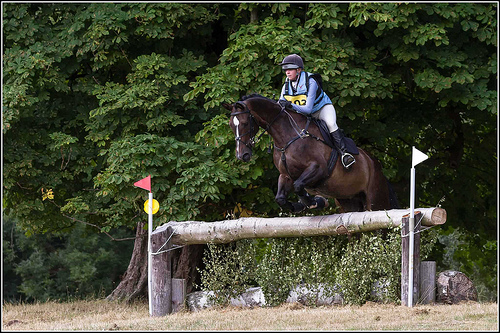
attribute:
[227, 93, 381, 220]
steed — brown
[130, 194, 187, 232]
pole — yellow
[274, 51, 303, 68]
helmet — blue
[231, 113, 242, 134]
mark — white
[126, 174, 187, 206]
flag — small, red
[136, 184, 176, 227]
sign — yellow, round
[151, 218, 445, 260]
log — wooden, birch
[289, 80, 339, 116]
jacket — blue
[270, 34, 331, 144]
jockey — small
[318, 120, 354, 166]
boot — black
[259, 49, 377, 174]
jockey — small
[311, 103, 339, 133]
pants — white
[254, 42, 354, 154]
jockey — small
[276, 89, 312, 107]
number — yellow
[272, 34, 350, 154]
jockey — small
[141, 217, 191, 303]
stump — wooden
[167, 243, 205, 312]
stump — wooden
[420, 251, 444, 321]
stump — wooden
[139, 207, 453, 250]
stump — wooden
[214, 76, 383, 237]
horse — dark brown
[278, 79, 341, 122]
clothes — blue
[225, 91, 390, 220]
horse — brown, black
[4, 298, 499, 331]
grass — dried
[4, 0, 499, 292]
leaves — green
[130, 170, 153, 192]
flag — red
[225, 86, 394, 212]
horse — brown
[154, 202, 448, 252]
log — vertical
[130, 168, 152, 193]
flag — red, small, triangular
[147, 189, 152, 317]
post — silver, metal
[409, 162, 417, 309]
post — metal, silver, small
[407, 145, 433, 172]
flag — small, white, triangle shaped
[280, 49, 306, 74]
safety helmet — dark, grey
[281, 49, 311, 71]
helmet — blue